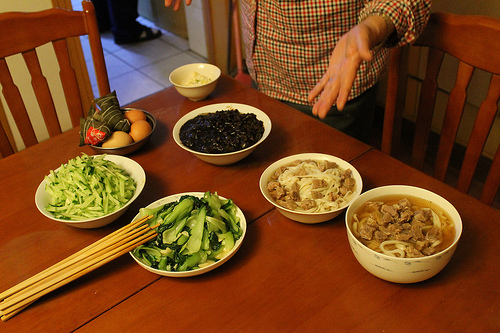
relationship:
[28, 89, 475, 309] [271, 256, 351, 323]
food on table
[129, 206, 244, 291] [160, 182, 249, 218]
bokchoy on plate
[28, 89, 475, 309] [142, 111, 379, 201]
eggs in bowl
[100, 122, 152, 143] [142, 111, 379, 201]
eggs in bowl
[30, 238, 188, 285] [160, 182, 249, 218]
chopstick on plate